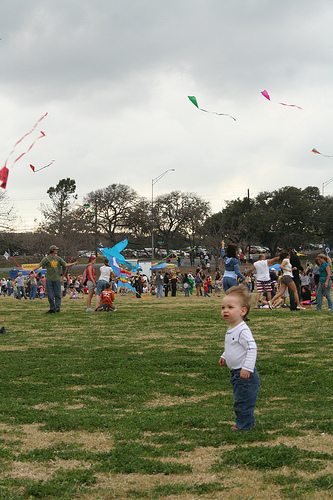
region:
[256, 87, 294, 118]
pink kite being flown in sky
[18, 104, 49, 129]
pink kite being flown in sky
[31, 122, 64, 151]
pink kite being flown in sky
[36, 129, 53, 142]
pink kite being flown in sky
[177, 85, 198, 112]
green kite being flown in sky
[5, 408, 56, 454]
short green grass on brown dirt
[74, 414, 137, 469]
short green grass on brown dirt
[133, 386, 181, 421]
short green grass on brown dirt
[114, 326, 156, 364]
short green grass on brown dirt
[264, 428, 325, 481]
short green grass on brown dirt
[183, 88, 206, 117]
green kite flown in ski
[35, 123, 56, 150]
red kite flown in ski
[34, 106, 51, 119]
red kite flown in ski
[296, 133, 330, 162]
red kite flown in ski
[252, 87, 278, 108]
red kite flown in ski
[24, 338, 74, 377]
short green grass and brown dirt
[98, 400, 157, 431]
short green grass and brown dirt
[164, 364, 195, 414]
short green grass and brown dirt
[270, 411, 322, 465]
short green grass and brown dirt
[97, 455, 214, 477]
short green grass and brown dirt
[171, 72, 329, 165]
Colorful kites flying in sky.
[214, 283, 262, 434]
Toddler standing alone in field.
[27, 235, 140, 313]
Man holding blue kite.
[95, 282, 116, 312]
Young boy in red shirt kneeling on grass.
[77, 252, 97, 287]
Woman wearing red headband and red sleeveless top.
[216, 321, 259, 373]
Toddler dressed in longsleeve white top.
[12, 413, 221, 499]
Patchy grass on ground.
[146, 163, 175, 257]
Lamp post standing next to street.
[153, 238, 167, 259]
Red stop sign with green traffic sign mounted above.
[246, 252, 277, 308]
Man dressed in white sleeveless shirt and red and white striped shorts.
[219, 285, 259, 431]
A child with wind blowing through their hair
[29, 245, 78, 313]
A man with a green shirt and ballcap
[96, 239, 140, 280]
A light blue kite with wings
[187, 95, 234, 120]
A green kite with a streaming tail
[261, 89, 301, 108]
A pink kite with a streaming tail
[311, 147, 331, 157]
A blue and red kite with a streaming tail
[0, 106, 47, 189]
A black and red kite with steaming tails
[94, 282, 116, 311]
A person kneeling with a red shirt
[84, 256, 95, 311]
A girl with a red tank top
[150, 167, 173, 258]
A lamp post that is not lit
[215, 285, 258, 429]
A baby standing in a field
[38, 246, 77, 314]
A man flying a kite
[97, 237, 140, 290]
A big blue kite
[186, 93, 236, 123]
A green kite flying in the sky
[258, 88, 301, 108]
A pink kite flying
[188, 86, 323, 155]
Three colorful kites flying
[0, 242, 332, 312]
A crowd of people in a grass field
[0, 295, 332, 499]
A grass field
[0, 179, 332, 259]
A cluster of trees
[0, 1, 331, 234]
A cloudy sky